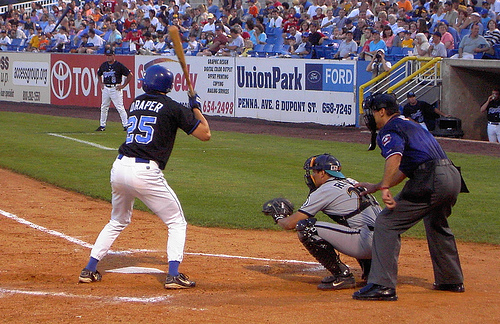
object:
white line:
[139, 245, 325, 265]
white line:
[4, 285, 152, 305]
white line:
[45, 132, 110, 153]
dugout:
[442, 56, 500, 143]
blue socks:
[167, 259, 181, 280]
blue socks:
[84, 255, 100, 273]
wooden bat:
[166, 23, 200, 100]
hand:
[185, 90, 203, 110]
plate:
[102, 262, 169, 276]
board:
[234, 56, 358, 126]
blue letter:
[250, 65, 258, 86]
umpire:
[348, 91, 468, 301]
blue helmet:
[140, 64, 177, 94]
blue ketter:
[235, 64, 248, 87]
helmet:
[135, 64, 174, 94]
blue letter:
[346, 103, 354, 115]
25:
[125, 114, 158, 146]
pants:
[89, 154, 188, 264]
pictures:
[0, 0, 500, 323]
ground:
[0, 108, 499, 323]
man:
[260, 152, 382, 295]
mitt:
[259, 195, 293, 222]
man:
[79, 63, 212, 287]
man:
[480, 86, 500, 145]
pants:
[416, 121, 430, 131]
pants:
[487, 122, 500, 144]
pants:
[100, 82, 131, 129]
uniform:
[296, 175, 388, 260]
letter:
[292, 65, 304, 89]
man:
[91, 47, 133, 132]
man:
[402, 90, 453, 134]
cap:
[101, 47, 117, 55]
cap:
[407, 90, 419, 98]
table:
[45, 126, 230, 153]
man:
[363, 48, 393, 92]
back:
[324, 176, 385, 243]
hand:
[358, 182, 381, 198]